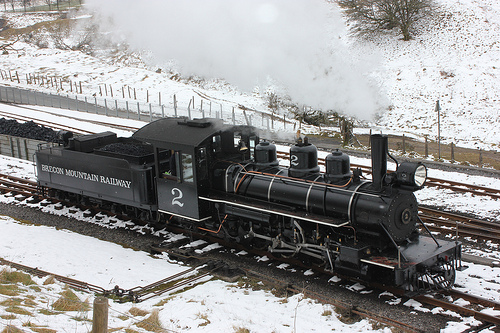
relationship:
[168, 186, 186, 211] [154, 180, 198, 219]
number on side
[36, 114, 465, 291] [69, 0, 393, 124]
locomotive has steam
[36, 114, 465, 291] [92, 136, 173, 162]
locomotive hauls coal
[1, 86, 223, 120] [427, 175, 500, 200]
fence on side of tracks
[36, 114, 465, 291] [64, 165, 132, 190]
locomotive belongs to mountain railway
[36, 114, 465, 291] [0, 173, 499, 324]
locomotive on top of track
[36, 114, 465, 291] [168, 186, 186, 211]
locomotive has number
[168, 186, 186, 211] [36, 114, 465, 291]
number printed on locomotive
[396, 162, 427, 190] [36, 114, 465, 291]
light on front of locomotive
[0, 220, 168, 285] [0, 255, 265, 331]
snow on top of ground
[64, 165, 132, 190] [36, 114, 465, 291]
name on side of locomotive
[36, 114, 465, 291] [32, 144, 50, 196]
locomotive has bumper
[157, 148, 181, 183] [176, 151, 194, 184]
engineer has window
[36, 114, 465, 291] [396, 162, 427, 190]
locomotive has light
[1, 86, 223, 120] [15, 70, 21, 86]
fence has post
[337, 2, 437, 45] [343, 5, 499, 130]
tree on side of hillside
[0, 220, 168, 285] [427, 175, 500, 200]
snow beside tracks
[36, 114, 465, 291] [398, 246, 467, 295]
locomotive has cattle guard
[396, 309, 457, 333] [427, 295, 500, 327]
gravel along tracks